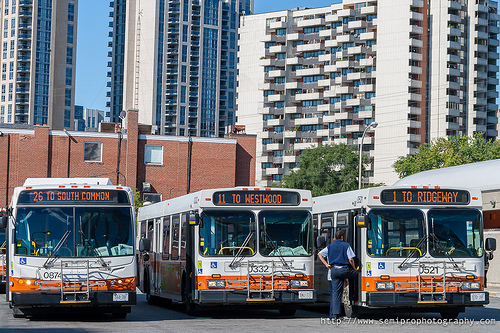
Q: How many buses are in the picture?
A: Three.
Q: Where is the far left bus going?
A: To South Common.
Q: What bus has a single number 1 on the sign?
A: Far right bus.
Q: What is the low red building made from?
A: Bricks.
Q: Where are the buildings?
A: Behind the buses.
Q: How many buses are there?
A: 3.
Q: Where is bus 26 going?
A: South common.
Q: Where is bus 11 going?
A: Westwood.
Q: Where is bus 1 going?
A: Ridgeway.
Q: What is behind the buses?
A: Red brick building.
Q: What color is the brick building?
A: Red.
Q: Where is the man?
A: Next to the bus.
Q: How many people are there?
A: 1.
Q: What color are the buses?
A: Orange and white.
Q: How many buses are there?
A: Three.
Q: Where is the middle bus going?
A: Westwood.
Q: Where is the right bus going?
A: Ridgeway.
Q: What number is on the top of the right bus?
A: One.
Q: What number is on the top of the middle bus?
A: Eleven.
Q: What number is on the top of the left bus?
A: Twenty Six.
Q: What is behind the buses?
A: Buildings.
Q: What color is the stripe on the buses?
A: Orange.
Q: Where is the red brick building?
A: Behind the buses.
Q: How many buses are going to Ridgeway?
A: 1.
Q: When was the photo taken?
A: Morning.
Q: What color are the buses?
A: White and orange.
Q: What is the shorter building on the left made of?
A: Brick.